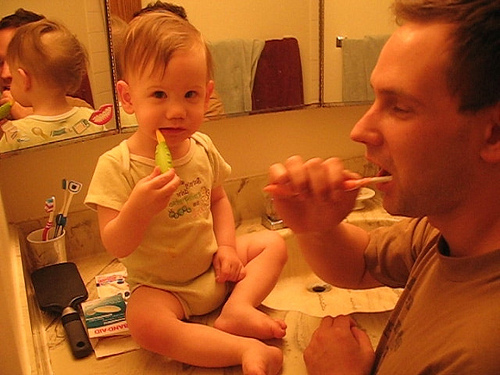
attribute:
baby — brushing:
[84, 11, 290, 374]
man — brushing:
[265, 2, 498, 374]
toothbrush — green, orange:
[43, 196, 57, 241]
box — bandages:
[78, 292, 141, 359]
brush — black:
[29, 261, 94, 361]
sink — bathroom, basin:
[261, 221, 403, 318]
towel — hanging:
[252, 36, 306, 119]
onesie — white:
[84, 131, 235, 321]